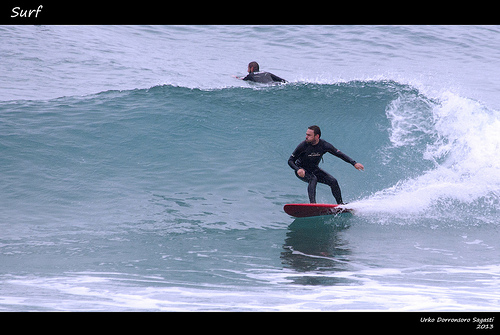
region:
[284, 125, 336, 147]
the guy has a beard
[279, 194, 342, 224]
surfboard is red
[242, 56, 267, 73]
this guys hair is black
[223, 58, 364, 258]
two surfers in the water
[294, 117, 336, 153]
this guy has brown hair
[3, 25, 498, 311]
the water is nice and blue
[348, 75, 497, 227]
the waves are white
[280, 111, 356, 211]
the wet suit is black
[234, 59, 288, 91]
the guy is laying on the board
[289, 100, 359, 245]
riding a surfboard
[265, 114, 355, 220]
man wearing black wet suit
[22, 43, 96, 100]
white clouds in blue sky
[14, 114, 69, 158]
white clouds in blue sky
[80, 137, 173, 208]
white clouds in blue sky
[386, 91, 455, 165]
white clouds in blue sky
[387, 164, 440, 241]
white clouds in blue sky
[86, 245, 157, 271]
white clouds in blue sky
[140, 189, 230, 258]
white clouds in blue sky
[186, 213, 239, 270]
white clouds in blue sky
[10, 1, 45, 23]
Word "surf" in white letters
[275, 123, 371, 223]
Man on a red surfboard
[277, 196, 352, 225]
Red surfboard on top of the water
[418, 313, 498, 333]
White photographer logo in the bottom corner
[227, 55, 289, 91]
Man swimming away from the camera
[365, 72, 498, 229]
White foam on top of the wave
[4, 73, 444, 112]
Peak of the blue wave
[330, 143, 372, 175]
Man's left arm out to the side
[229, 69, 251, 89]
Man's left arm in front of him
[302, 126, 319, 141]
Man's head with wet hair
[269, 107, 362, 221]
man surfing in ocean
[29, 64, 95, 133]
white clouds in blue sky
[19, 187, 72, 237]
white clouds in blue sky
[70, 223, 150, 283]
white clouds in blue sky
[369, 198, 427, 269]
white clouds in blue sky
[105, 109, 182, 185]
white clouds in blue sky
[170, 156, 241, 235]
white clouds in blue sky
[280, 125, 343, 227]
person surfing in ocean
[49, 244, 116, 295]
white clouds in blue sky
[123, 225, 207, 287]
white clouds in blue sky